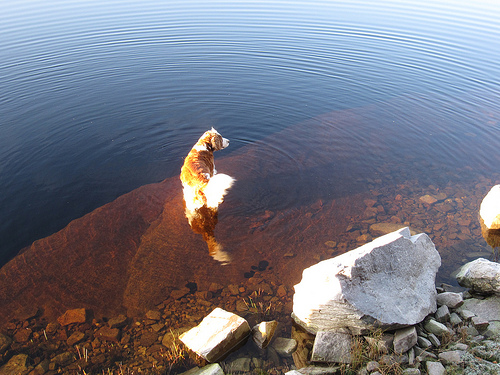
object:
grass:
[339, 320, 405, 375]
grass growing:
[243, 288, 272, 315]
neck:
[191, 143, 214, 153]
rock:
[478, 183, 500, 249]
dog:
[179, 126, 238, 265]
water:
[0, 0, 500, 375]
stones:
[393, 326, 418, 354]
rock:
[291, 226, 442, 335]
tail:
[202, 173, 238, 209]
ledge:
[0, 106, 500, 375]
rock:
[178, 307, 252, 363]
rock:
[450, 257, 500, 297]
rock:
[310, 328, 351, 363]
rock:
[57, 308, 86, 327]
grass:
[160, 328, 196, 374]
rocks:
[245, 180, 498, 375]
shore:
[177, 184, 499, 374]